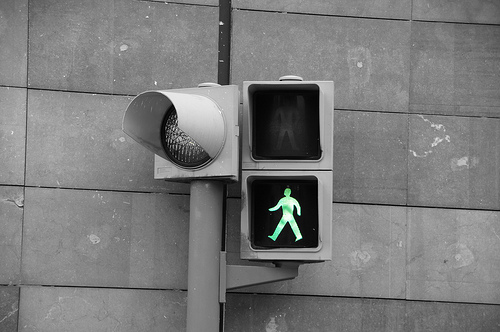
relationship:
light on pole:
[122, 84, 242, 179] [185, 180, 224, 331]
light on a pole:
[122, 84, 242, 179] [185, 180, 224, 331]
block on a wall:
[2, 0, 28, 87] [0, 1, 500, 332]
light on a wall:
[122, 84, 242, 179] [0, 1, 500, 332]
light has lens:
[122, 84, 242, 179] [161, 106, 209, 168]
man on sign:
[271, 97, 302, 152] [242, 81, 333, 261]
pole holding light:
[185, 180, 224, 331] [122, 84, 242, 179]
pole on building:
[185, 180, 224, 331] [1, 0, 498, 332]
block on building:
[2, 0, 28, 87] [1, 0, 498, 332]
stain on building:
[403, 113, 454, 160] [1, 0, 498, 332]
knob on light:
[278, 75, 304, 80] [122, 84, 242, 179]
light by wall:
[122, 84, 242, 179] [0, 1, 500, 332]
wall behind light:
[0, 1, 500, 332] [122, 84, 242, 179]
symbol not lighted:
[266, 188, 306, 241] [266, 188, 306, 241]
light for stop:
[122, 84, 242, 179] [266, 188, 306, 241]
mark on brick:
[403, 113, 454, 160] [2, 0, 28, 87]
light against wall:
[122, 84, 242, 179] [0, 1, 500, 332]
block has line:
[2, 0, 28, 87] [220, 2, 230, 84]